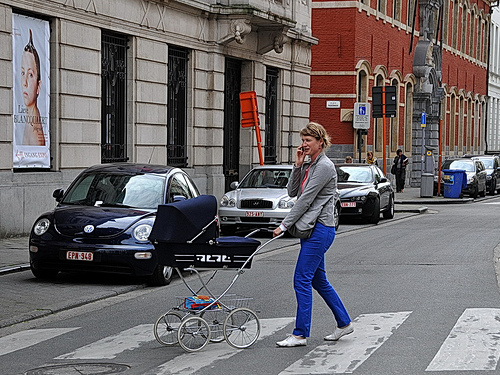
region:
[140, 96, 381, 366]
The woman is pushing a baby carriage.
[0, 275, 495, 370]
A crosswalk.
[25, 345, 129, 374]
A manhole.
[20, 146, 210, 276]
A Volkswagon Beetle.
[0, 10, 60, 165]
An advertisement covering a window.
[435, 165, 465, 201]
A blue garbage can.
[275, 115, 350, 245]
The woman is on the phone.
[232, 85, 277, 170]
An orange street sign.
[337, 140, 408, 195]
People walking down the sidewalk.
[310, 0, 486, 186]
A brick building.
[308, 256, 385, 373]
the road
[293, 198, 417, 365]
the road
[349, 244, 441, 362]
the road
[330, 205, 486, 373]
the road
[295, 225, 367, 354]
the road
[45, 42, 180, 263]
the car is black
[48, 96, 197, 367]
the car is black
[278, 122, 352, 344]
the woman crosses the street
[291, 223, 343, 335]
the woman has blue pants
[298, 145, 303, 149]
the woman is on the phone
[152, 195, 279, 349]
the woman pushes a stroller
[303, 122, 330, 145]
the woman is blonde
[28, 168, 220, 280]
the car is a beetle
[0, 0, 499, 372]
the scene takes place outdoors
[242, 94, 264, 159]
the sign is red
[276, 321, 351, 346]
the woman wears white shoes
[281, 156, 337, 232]
the woman wears a sweater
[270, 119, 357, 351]
lady wearing blue and gray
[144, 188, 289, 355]
blue and silver baby stroller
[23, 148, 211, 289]
small navy blue car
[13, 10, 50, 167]
large white sign with photo of person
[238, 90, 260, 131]
back of metal orange sign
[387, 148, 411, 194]
person wearing black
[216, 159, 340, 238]
silver car parked on street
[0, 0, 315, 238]
large gray building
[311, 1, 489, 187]
large brick red building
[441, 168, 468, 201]
blue plastic trash can